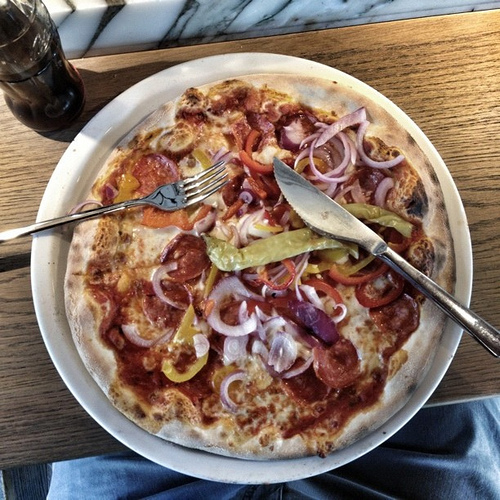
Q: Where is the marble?
A: Under the wood.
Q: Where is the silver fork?
A: Bowl.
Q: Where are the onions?
A: In bowl.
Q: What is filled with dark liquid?
A: A bottle.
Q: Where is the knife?
A: In bowl.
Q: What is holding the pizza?
A: A platter.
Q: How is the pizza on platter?
A: Uneaten.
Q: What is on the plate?
A: Pizza.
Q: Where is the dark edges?
A: The crust.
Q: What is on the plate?
A: Uncut pizza.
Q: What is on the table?
A: Plate of pizza.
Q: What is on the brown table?
A: Plate of pizza.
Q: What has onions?
A: Cooked pizza.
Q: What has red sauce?
A: Pizza.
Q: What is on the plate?
A: Stainless steel knife.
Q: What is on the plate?
A: Thin pizza.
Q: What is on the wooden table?
A: White plate.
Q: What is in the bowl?
A: Pizza.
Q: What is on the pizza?
A: Vegetables.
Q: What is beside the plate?
A: Soda.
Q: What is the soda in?
A: Glass bottle.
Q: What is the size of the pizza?
A: Personal size.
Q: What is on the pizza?
A: Red onions.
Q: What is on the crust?
A: Cheese.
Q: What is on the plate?
A: Pizza.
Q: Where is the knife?
A: On the plate.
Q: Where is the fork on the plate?
A: On the right side.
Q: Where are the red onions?
A: On the pizza.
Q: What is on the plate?
A: A pizza.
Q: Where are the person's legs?
A: Under the tables.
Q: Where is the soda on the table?
A: On the left side.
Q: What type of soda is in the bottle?
A: Cola.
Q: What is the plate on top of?
A: A table.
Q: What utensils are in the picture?
A: Fork and knife.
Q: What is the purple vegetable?
A: Onion.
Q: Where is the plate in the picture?
A: The center.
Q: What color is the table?
A: Brown.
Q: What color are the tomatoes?
A: Red.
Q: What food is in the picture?
A: Pizza.